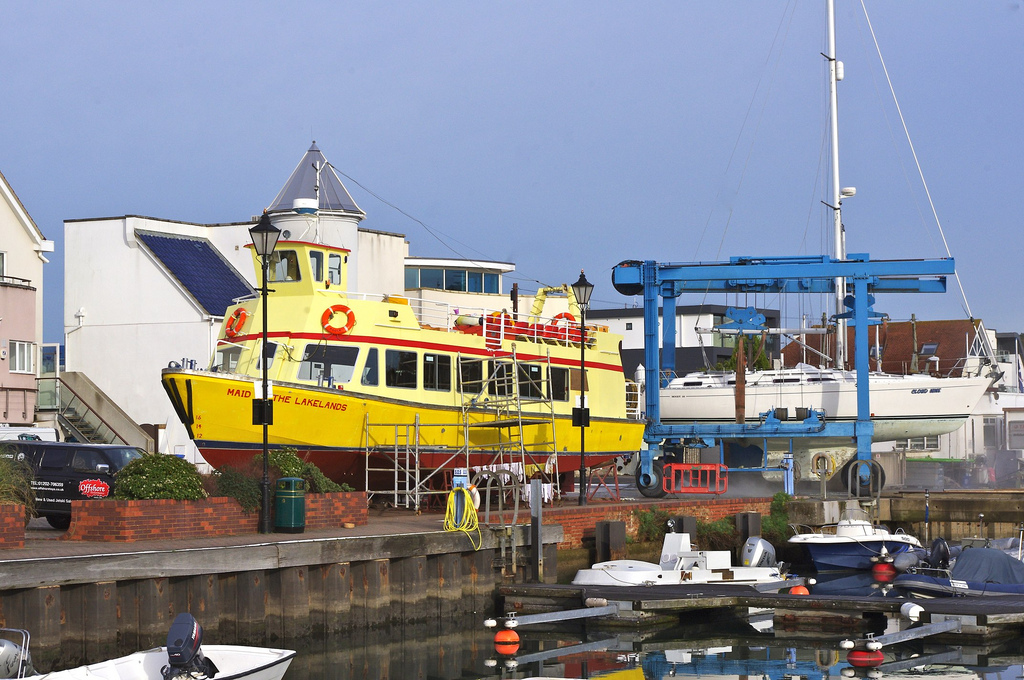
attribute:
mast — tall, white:
[815, 1, 859, 367]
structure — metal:
[609, 247, 960, 492]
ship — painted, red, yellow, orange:
[158, 152, 651, 509]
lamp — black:
[247, 214, 284, 273]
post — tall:
[260, 255, 280, 530]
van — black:
[3, 437, 129, 528]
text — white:
[23, 476, 63, 503]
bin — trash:
[269, 474, 317, 546]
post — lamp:
[247, 214, 291, 543]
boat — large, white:
[602, 250, 1016, 452]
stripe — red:
[231, 318, 630, 379]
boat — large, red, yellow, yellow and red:
[153, 236, 657, 507]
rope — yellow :
[440, 478, 488, 533]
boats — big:
[514, 510, 990, 657]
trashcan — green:
[263, 463, 313, 533]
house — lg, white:
[49, 141, 533, 470]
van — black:
[22, 431, 152, 525]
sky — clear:
[285, 13, 610, 117]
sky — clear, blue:
[26, 13, 420, 115]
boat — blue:
[875, 532, 992, 626]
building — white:
[36, 197, 611, 649]